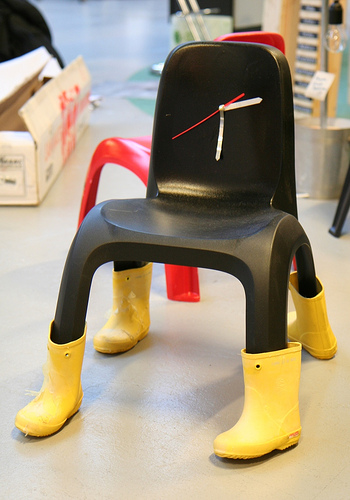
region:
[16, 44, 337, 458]
black plastic chair with yellow rain boots on legs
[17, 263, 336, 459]
four yellow rainboots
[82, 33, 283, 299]
red plastic chair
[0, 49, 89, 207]
open cardboard box on left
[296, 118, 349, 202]
metal bucket on right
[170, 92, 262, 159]
red strip and white zip tie on black chair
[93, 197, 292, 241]
seat of the black chair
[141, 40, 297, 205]
back of the black chair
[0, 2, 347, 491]
painted concrete floor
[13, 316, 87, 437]
yellow boot on front right leg.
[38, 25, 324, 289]
a chair with yellow boots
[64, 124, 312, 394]
this scene is comical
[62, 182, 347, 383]
a black chair with yellow boots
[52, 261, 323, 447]
the boots are rain boots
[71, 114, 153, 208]
a red chair in the scene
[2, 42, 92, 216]
a white box n the room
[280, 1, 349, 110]
a wooden area in the room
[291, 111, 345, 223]
a waste paper basket by the wall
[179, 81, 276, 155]
a red straw on the chair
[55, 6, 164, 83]
a light blue background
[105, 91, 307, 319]
black chair on floor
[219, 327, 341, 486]
yellow boots on legs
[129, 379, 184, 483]
floor is off white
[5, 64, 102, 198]
white box behind chairs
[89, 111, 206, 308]
red chair behind black chair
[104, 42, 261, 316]
red chair is plastic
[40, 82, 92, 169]
red label on box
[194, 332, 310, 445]
light yellow rubber boots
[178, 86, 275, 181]
clock image on black chair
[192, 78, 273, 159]
white hands on clock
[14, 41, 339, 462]
a small black plastic chair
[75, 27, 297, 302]
a small red plastic chair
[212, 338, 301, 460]
a yellow boot on a chair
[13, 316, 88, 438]
a yellow boot on a chair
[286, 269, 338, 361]
a yellow boot on a chair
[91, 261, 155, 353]
a yellow boot on a chair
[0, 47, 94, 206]
a white cardboard box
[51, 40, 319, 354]
a small black chair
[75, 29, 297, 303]
a small red chair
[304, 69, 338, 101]
a post-it note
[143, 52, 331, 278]
Clock on the chair.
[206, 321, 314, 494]
Boot on the chair.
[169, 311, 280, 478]
Yellow boot on the chair.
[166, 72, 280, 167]
hands on the clock.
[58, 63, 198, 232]
Red chair in the background.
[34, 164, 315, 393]
Black chair on the ground.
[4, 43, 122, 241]
Box on the floor.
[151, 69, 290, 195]
Red and white hands.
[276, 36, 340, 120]
Sign on the chair.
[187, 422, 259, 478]
Bottom of the boot